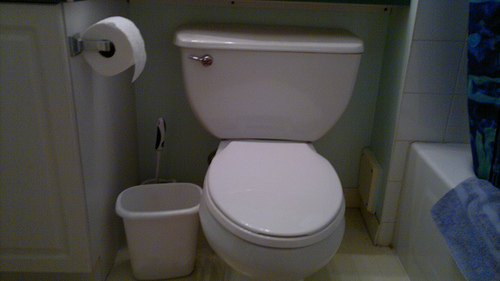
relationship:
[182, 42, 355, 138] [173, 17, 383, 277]
tank on bowl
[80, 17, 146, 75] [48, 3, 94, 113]
roll on wall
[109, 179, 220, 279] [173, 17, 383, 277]
bin next to bowl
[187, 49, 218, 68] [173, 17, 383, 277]
handle on bowl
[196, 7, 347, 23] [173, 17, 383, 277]
wall behind bowl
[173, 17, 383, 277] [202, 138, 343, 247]
bowl with seat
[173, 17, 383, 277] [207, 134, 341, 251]
bowl with cover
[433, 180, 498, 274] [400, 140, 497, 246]
towel over bathtub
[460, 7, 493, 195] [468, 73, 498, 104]
curtain with pattern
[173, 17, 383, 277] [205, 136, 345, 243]
bowl with lid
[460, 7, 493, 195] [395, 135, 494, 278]
curtain in bath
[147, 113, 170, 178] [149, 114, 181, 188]
handle of brush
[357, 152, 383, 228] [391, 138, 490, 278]
access near bathtub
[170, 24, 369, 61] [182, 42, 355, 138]
cover of tank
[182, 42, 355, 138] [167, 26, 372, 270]
tank of commode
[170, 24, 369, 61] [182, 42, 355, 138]
cover for tank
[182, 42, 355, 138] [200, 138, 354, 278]
tank of bowl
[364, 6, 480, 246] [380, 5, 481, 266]
tiles on wall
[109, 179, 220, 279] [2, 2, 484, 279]
bin in bathroom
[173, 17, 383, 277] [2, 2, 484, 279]
bowl in bathroom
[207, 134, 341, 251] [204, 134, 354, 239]
cover of seat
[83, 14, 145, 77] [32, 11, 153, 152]
paper on wall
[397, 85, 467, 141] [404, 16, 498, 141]
tile on wall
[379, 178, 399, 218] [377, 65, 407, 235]
tile on wall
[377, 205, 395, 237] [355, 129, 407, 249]
tile on wall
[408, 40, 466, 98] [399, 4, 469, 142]
tile on wall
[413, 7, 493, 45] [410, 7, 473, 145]
tile on wall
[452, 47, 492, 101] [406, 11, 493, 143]
tile on wall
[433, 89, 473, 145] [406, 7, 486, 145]
tile on wall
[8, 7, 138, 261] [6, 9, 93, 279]
cabinet has door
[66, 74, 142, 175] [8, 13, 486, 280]
wall side building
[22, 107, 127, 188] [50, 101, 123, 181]
wall on building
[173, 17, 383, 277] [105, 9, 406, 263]
bowl in bathroom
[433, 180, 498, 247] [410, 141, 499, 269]
towel on bathtub